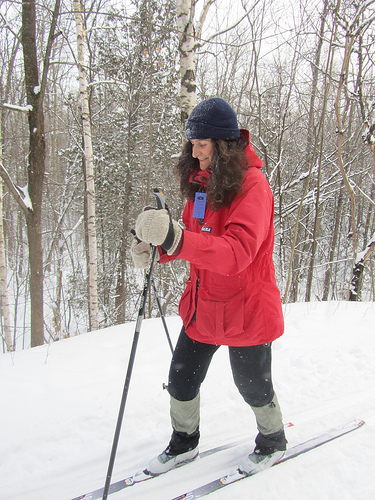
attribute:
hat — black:
[182, 97, 244, 143]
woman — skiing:
[128, 94, 290, 484]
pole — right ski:
[148, 276, 176, 348]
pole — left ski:
[98, 243, 157, 499]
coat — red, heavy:
[167, 129, 284, 351]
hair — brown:
[205, 133, 248, 207]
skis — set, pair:
[63, 410, 369, 500]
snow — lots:
[3, 300, 372, 494]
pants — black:
[165, 323, 285, 454]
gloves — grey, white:
[132, 184, 187, 267]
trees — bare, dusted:
[1, 8, 373, 330]